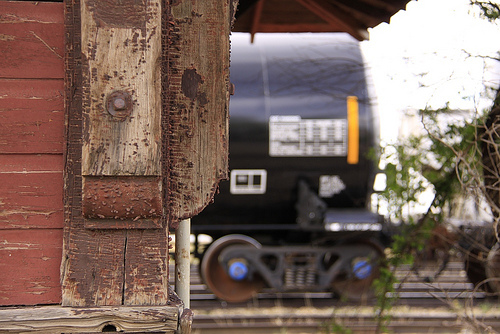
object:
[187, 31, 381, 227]
tanker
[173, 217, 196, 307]
pipe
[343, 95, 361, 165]
line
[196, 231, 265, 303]
wheel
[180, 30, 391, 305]
train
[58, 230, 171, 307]
piece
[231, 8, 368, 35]
support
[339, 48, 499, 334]
leave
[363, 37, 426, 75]
light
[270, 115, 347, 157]
panel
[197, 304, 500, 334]
platform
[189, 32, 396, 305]
locomotive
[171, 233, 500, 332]
rail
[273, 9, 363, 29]
roof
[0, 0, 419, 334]
building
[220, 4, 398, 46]
underhand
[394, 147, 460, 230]
weed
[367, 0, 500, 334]
shrub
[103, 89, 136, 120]
bolt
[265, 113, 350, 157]
sticker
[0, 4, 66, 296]
paint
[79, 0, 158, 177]
wood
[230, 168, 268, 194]
sign